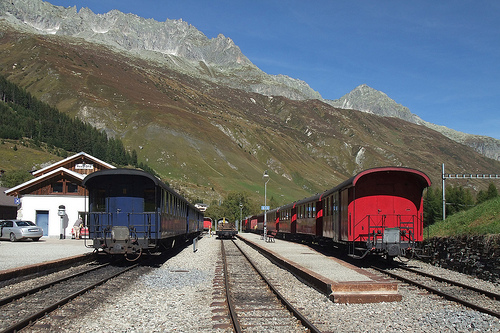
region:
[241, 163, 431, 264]
a red train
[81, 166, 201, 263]
a blue train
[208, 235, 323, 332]
a pair of rusty train tracks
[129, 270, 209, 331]
a patch of rock gravel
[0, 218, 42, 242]
a silver car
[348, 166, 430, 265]
the back of a red train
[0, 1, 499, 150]
grey jagged mountains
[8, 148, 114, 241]
a brown and white building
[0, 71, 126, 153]
green pine trees on a hill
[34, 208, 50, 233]
a blue door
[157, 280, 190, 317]
pebbles between the tracks.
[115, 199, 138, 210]
blue paint on train.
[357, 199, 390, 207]
red paint on train.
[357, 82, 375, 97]
top of the mountain.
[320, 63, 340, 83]
clouds in the sky.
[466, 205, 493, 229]
grass on the slope.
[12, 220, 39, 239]
vehicle parked near the building.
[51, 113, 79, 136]
trees on the slope.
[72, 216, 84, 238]
person near the building.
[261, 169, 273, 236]
pole near the train.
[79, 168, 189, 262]
a blue caboose train car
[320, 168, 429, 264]
a red caboose train car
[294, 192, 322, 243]
a red passenger train car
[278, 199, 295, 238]
a red passenger train car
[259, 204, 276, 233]
a red passenger train car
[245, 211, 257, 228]
a red passenger train car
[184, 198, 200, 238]
a blue passenger train car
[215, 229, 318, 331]
a set of train tracks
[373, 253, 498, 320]
a set of train tracks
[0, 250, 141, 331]
a set of train tracks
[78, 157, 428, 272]
separate red and blue trains on tracks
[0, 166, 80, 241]
grey car parked by building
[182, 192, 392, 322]
track and median between trains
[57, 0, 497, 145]
clear blue sky over mountains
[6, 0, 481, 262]
dark slopes under grey mountaintops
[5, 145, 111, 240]
brown and white building with two roofs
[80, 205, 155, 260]
black railing in back of train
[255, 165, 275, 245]
pole with sign next to bench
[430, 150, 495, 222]
elevated structure on hill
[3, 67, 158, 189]
dense trees along a slope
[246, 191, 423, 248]
Red train is long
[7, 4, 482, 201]
Large mountain in background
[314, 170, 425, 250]
Caboose is relatively tall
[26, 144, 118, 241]
Small mountain building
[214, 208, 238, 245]
Part of third train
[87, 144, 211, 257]
Long blue train on left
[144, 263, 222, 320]
Gravel between tracks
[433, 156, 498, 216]
Track of lights beside trains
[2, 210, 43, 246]
Parked silver car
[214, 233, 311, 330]
Middle row of tracks